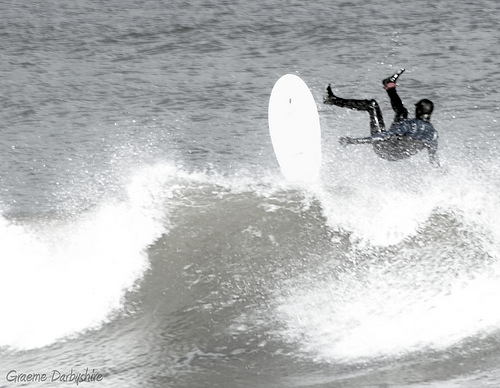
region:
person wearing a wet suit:
[312, 49, 452, 181]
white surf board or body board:
[265, 60, 326, 195]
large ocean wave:
[107, 123, 254, 308]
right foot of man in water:
[380, 59, 407, 106]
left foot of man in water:
[323, 82, 341, 111]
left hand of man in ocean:
[334, 128, 351, 154]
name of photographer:
[4, 366, 111, 385]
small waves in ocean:
[12, 9, 257, 99]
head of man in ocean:
[411, 98, 436, 124]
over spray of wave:
[371, 29, 400, 74]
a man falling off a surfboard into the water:
[248, 49, 465, 214]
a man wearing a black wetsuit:
[323, 54, 456, 188]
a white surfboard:
[252, 70, 329, 202]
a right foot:
[376, 64, 411, 91]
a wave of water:
[2, 157, 499, 386]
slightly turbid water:
[3, 3, 238, 88]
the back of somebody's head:
[410, 95, 440, 125]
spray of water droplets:
[52, 129, 180, 201]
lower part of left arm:
[336, 122, 376, 154]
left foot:
[323, 80, 342, 113]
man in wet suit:
[314, 67, 456, 184]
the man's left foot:
[320, 79, 342, 110]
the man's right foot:
[378, 67, 415, 88]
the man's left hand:
[334, 133, 354, 155]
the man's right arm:
[425, 139, 453, 178]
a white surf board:
[258, 71, 340, 202]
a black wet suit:
[327, 78, 446, 178]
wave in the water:
[41, 131, 488, 348]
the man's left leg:
[318, 80, 400, 160]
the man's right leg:
[375, 70, 423, 143]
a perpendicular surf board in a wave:
[263, 68, 323, 199]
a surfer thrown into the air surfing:
[300, 62, 449, 200]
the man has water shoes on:
[323, 63, 408, 110]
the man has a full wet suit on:
[334, 85, 446, 175]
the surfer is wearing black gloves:
[336, 131, 448, 179]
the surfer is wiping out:
[263, 69, 448, 208]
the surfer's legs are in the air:
[321, 57, 441, 173]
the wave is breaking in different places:
[5, 142, 499, 386]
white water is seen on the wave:
[6, 123, 499, 365]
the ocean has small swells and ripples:
[3, 4, 498, 155]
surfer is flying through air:
[261, 19, 469, 214]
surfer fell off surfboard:
[243, 41, 494, 241]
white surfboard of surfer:
[252, 53, 494, 187]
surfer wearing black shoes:
[307, 63, 479, 213]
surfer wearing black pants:
[302, 51, 480, 180]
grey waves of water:
[35, 141, 246, 367]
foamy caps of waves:
[15, 145, 257, 327]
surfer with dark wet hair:
[282, 16, 491, 205]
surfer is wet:
[305, 56, 455, 196]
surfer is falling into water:
[231, 51, 454, 209]